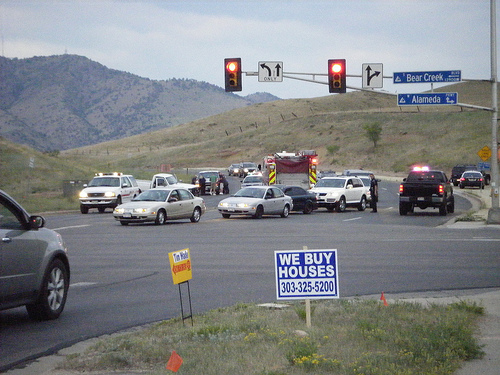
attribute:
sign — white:
[273, 250, 338, 299]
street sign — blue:
[398, 94, 457, 104]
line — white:
[343, 215, 366, 223]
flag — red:
[276, 158, 311, 172]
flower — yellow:
[302, 357, 308, 368]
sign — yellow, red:
[168, 247, 194, 283]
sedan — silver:
[218, 185, 294, 220]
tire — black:
[156, 209, 167, 224]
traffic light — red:
[224, 63, 240, 72]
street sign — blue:
[393, 71, 463, 83]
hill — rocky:
[0, 49, 288, 151]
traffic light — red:
[331, 65, 341, 72]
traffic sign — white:
[361, 62, 384, 91]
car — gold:
[114, 187, 207, 225]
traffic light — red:
[225, 59, 242, 91]